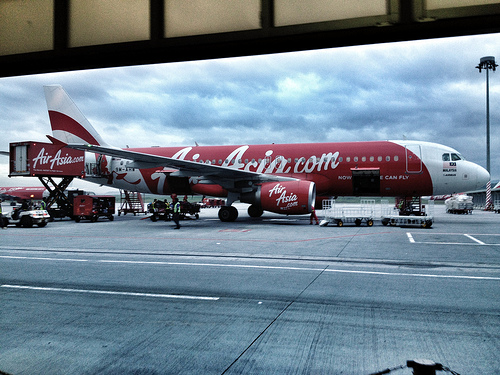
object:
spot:
[257, 301, 264, 304]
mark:
[215, 243, 222, 246]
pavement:
[0, 281, 500, 375]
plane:
[44, 82, 490, 222]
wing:
[45, 135, 308, 208]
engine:
[256, 180, 316, 215]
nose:
[455, 160, 491, 195]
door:
[406, 145, 422, 174]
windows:
[386, 155, 390, 161]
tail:
[42, 86, 112, 185]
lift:
[8, 142, 82, 210]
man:
[170, 193, 180, 230]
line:
[0, 284, 220, 301]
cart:
[71, 195, 114, 222]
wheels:
[218, 205, 238, 221]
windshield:
[451, 154, 461, 161]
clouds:
[298, 86, 403, 138]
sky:
[0, 34, 500, 184]